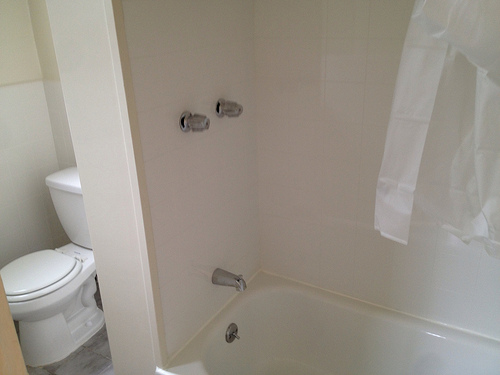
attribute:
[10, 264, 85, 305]
seat — toilet , white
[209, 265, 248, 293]
faucet — silver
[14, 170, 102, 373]
toilet — white, tank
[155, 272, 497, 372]
tub — white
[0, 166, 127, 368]
toilet — tank cover, white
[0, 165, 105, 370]
toilet — white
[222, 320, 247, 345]
stopper — silver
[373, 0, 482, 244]
curtain — clear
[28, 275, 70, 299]
cover — white, toilet seat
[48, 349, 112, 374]
tile — white